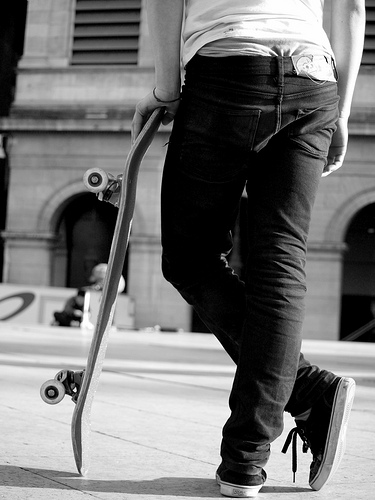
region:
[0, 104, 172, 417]
this is a skate board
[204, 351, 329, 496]
the legs are crossed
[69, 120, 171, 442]
the skate board is upright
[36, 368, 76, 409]
these are the boards wheels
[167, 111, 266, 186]
this is the back pocket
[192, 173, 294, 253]
the trousers are black in color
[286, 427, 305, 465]
the laces are lying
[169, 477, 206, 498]
this is the shadow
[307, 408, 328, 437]
the shoe is black in color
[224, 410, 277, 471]
the jeans is folded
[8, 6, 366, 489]
a black and white photo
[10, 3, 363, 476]
a scene outdoors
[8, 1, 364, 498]
a person standing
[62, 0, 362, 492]
a person resting on a skateboard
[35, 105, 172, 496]
a skateboard being held by a person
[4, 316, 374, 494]
a concrete floor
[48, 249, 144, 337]
a person in the distance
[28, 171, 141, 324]
a door to the building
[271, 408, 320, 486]
shoelaces dangling downwards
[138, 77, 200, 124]
a bracelet on the wrist of the person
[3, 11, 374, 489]
Photo is in black and white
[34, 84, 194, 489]
Person is holding a skateboard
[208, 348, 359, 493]
Person's shoes are black and white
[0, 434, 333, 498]
Person is casting a shadow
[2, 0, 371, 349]
Building is in the background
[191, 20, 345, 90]
Person's pants are sagging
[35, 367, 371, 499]
Person is standing on the sidewalk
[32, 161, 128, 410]
Skateboard wheels are white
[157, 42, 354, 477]
Person is wearing jeans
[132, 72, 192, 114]
Person is wearing a black wristband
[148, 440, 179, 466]
part of a floor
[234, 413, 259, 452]
part of a jeans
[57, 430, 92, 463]
edge of a skate board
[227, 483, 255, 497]
sole of a shoe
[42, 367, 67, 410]
part of a wheel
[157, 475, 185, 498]
part of a shade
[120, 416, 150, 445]
part of a floor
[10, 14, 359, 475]
Black and white picture.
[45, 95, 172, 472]
Person is holding the skateboard.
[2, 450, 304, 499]
Shadow falls on the ground.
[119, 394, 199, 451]
Pathway is grey color.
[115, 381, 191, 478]
Pathway is made of concrete.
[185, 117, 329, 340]
Person is wearing black pant.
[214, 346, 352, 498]
Shoes are white and black color.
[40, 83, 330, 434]
Two person are in picture.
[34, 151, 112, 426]
Wheels are white color.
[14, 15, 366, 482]
Day time picture.